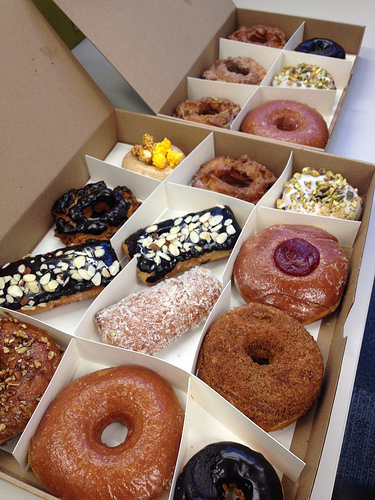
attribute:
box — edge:
[54, 0, 365, 150]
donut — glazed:
[28, 363, 185, 499]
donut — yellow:
[122, 125, 186, 183]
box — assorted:
[84, 5, 364, 145]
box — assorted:
[11, 67, 331, 498]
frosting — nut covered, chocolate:
[122, 200, 246, 276]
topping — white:
[117, 289, 192, 360]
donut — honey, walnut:
[0, 315, 66, 449]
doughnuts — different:
[33, 177, 224, 329]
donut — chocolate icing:
[230, 439, 305, 498]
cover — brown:
[0, 0, 114, 243]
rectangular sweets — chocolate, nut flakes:
[122, 203, 243, 279]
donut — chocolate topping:
[59, 192, 114, 230]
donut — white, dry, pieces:
[270, 157, 372, 231]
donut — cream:
[197, 155, 272, 201]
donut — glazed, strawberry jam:
[233, 223, 350, 325]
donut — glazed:
[24, 348, 168, 494]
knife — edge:
[33, 1, 155, 118]